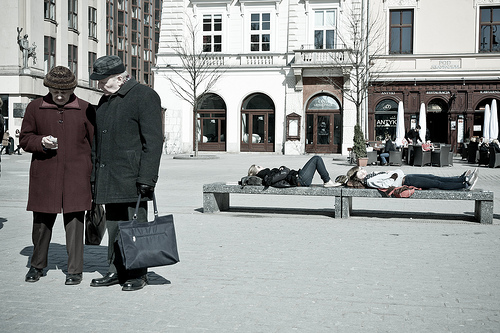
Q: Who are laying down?
A: Two women.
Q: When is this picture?
A: During the day.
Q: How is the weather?
A: Cool and sunny.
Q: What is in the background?
A: A cafe.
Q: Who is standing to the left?
A: An older woman and man.